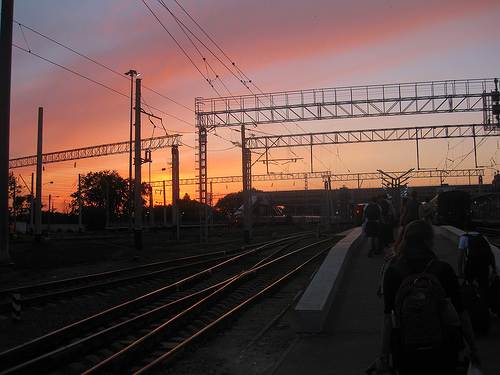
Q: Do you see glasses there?
A: No, there are no glasses.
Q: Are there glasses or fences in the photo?
A: No, there are no glasses or fences.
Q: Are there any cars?
A: No, there are no cars.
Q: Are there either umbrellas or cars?
A: No, there are no cars or umbrellas.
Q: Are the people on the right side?
A: Yes, the people are on the right of the image.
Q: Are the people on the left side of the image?
A: No, the people are on the right of the image.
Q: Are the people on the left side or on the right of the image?
A: The people are on the right of the image.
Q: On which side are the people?
A: The people are on the right of the image.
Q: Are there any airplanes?
A: No, there are no airplanes.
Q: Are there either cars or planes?
A: No, there are no planes or cars.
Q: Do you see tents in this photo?
A: No, there are no tents.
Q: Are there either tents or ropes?
A: No, there are no tents or ropes.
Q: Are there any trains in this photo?
A: Yes, there is a train.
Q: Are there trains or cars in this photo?
A: Yes, there is a train.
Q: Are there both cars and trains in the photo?
A: No, there is a train but no cars.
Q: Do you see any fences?
A: No, there are no fences.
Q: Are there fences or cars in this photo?
A: No, there are no fences or cars.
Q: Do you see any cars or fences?
A: No, there are no fences or cars.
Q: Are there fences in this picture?
A: No, there are no fences.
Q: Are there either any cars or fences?
A: No, there are no fences or cars.